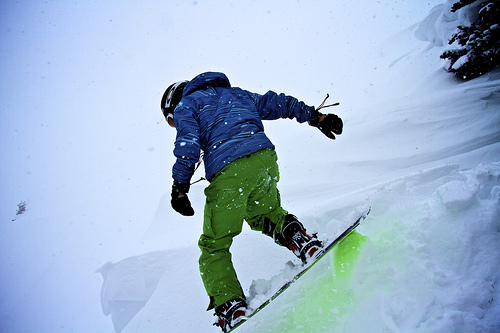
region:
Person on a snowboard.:
[126, 52, 458, 332]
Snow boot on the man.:
[203, 234, 260, 311]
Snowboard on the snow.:
[155, 189, 398, 330]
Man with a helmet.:
[153, 46, 433, 281]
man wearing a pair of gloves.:
[131, 62, 424, 277]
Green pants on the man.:
[198, 139, 317, 288]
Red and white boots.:
[253, 180, 325, 277]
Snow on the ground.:
[280, 124, 487, 289]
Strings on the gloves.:
[320, 77, 337, 135]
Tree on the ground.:
[397, 34, 498, 91]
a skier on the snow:
[144, 58, 371, 322]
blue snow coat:
[168, 84, 289, 178]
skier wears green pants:
[136, 54, 372, 331]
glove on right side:
[300, 100, 352, 143]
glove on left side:
[163, 180, 193, 216]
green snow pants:
[193, 148, 293, 303]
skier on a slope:
[54, 56, 489, 318]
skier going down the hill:
[28, 60, 477, 325]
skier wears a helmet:
[142, 60, 270, 178]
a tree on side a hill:
[416, 5, 498, 117]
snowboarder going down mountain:
[138, 73, 375, 325]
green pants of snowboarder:
[198, 173, 294, 288]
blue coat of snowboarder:
[168, 76, 293, 178]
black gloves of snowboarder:
[166, 116, 346, 214]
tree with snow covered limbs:
[436, 6, 493, 82]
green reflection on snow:
[261, 232, 385, 322]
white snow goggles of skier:
[156, 78, 178, 125]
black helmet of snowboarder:
[161, 80, 186, 108]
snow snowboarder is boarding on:
[108, 204, 498, 331]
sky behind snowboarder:
[9, 11, 464, 324]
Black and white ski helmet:
[157, 73, 183, 111]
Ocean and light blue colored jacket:
[175, 65, 270, 155]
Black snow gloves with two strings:
[305, 90, 340, 145]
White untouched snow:
[350, 80, 485, 150]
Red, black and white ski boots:
[280, 220, 325, 260]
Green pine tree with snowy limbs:
[440, 0, 495, 90]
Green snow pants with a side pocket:
[195, 156, 276, 301]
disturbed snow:
[372, 188, 496, 324]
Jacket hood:
[179, 69, 236, 97]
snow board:
[251, 259, 336, 306]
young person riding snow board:
[148, 66, 353, 303]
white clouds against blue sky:
[16, 16, 93, 50]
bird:
[5, 189, 39, 234]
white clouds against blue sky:
[12, 54, 59, 106]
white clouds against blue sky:
[29, 123, 100, 170]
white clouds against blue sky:
[78, 201, 129, 219]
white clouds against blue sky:
[88, 104, 129, 161]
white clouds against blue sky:
[89, 17, 127, 55]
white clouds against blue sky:
[231, 19, 293, 54]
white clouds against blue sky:
[321, 30, 398, 74]